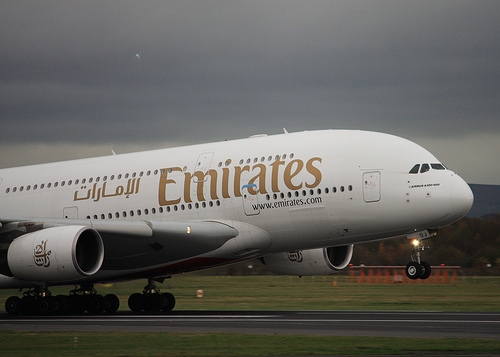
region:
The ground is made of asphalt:
[114, 302, 455, 332]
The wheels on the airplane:
[122, 279, 182, 320]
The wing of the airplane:
[7, 193, 245, 300]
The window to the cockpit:
[401, 143, 448, 184]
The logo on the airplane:
[140, 151, 331, 209]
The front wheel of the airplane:
[394, 223, 436, 285]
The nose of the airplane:
[364, 118, 478, 263]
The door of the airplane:
[350, 166, 388, 211]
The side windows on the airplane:
[261, 176, 356, 208]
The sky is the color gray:
[37, 21, 398, 123]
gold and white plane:
[4, 116, 469, 288]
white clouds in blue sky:
[8, 14, 31, 43]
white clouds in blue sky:
[154, 80, 189, 121]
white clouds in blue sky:
[384, 15, 435, 61]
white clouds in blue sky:
[360, 101, 415, 123]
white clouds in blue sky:
[278, 52, 336, 91]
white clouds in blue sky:
[179, 16, 227, 61]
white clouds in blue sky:
[188, 71, 235, 107]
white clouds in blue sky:
[108, 24, 163, 66]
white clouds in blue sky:
[110, 66, 156, 112]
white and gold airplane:
[14, 113, 471, 273]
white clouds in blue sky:
[19, 17, 59, 55]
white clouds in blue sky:
[97, 36, 156, 84]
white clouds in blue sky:
[251, 52, 313, 104]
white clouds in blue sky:
[372, 2, 419, 65]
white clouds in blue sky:
[146, 77, 207, 110]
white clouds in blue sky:
[403, 45, 466, 91]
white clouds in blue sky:
[24, 34, 85, 80]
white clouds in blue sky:
[154, 26, 189, 65]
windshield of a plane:
[407, 154, 451, 174]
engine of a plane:
[1, 219, 107, 289]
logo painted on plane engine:
[27, 237, 55, 272]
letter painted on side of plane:
[302, 153, 326, 191]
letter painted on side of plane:
[282, 158, 306, 190]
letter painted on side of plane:
[265, 152, 287, 194]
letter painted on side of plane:
[246, 158, 269, 199]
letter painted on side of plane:
[228, 158, 252, 203]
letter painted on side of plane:
[218, 155, 235, 202]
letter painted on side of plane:
[181, 165, 222, 208]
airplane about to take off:
[1, 116, 489, 313]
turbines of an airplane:
[230, 227, 369, 275]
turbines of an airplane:
[0, 221, 120, 279]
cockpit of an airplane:
[358, 113, 480, 237]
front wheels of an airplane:
[389, 228, 451, 285]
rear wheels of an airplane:
[2, 280, 191, 321]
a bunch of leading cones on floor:
[350, 261, 462, 286]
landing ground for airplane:
[3, 302, 488, 339]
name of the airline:
[151, 142, 326, 214]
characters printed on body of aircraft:
[62, 167, 147, 206]